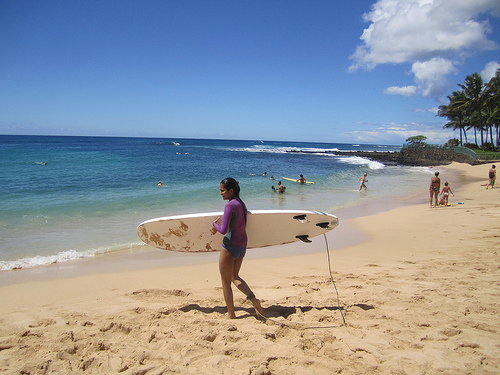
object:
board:
[136, 209, 339, 253]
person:
[486, 165, 497, 189]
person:
[296, 174, 306, 185]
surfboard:
[282, 176, 314, 184]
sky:
[3, 3, 497, 147]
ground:
[0, 194, 499, 374]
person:
[158, 180, 169, 187]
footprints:
[370, 324, 395, 336]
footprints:
[160, 307, 177, 316]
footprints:
[436, 322, 460, 338]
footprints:
[351, 345, 376, 355]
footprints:
[401, 255, 414, 267]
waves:
[118, 156, 214, 177]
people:
[271, 185, 278, 192]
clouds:
[346, 0, 499, 149]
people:
[277, 180, 284, 193]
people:
[428, 171, 442, 208]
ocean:
[0, 135, 400, 272]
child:
[440, 181, 455, 206]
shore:
[2, 154, 498, 369]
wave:
[337, 152, 383, 167]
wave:
[248, 145, 341, 156]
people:
[358, 172, 368, 191]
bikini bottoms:
[222, 243, 247, 259]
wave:
[0, 238, 139, 275]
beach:
[1, 153, 498, 373]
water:
[2, 139, 407, 257]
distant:
[0, 131, 104, 160]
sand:
[0, 226, 498, 370]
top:
[212, 198, 248, 247]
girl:
[211, 178, 263, 318]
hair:
[221, 178, 248, 226]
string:
[322, 235, 347, 327]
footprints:
[204, 333, 219, 342]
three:
[427, 164, 497, 207]